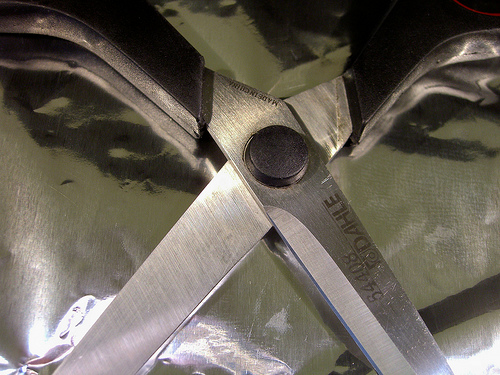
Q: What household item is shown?
A: Scissors.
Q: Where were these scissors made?
A: China.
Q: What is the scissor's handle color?
A: Black.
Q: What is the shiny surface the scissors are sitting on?
A: Tinfoil.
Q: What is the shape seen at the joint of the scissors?
A: Circle.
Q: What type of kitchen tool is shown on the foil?
A: Scissors.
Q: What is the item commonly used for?
A: Cutting.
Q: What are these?
A: Metal blades.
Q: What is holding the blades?
A: A connector.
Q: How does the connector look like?
A: Black.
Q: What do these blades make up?
A: A pair of scissors.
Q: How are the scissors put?
A: Opened.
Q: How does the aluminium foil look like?
A: Shiny.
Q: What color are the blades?
A: Silver.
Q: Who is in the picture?
A: There is nobody.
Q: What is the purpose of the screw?
A: Hold scissor together.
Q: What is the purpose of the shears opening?
A: For cutting.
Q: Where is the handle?
A: Above the blade.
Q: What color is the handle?
A: Black.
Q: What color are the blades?
A: Silver.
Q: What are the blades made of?
A: Metal.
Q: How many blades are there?
A: Two.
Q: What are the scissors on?
A: Foil.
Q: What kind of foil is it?
A: Aluminum foil.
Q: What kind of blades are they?
A: Scissor blades.